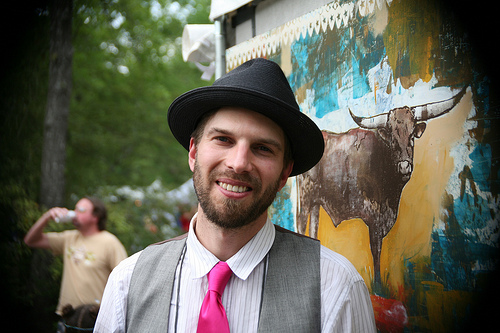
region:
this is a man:
[98, 74, 385, 331]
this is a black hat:
[131, 40, 331, 192]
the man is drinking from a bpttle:
[40, 201, 138, 328]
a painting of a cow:
[299, 96, 455, 257]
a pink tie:
[184, 264, 244, 329]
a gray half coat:
[134, 234, 333, 331]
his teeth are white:
[209, 169, 259, 209]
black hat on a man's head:
[161, 54, 329, 180]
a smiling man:
[93, 52, 383, 332]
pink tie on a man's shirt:
[189, 255, 232, 332]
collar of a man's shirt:
[178, 210, 283, 281]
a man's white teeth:
[216, 181, 248, 196]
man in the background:
[18, 191, 138, 331]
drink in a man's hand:
[53, 210, 75, 225]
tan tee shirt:
[52, 228, 131, 318]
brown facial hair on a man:
[188, 150, 286, 223]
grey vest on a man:
[124, 233, 317, 332]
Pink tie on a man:
[186, 255, 241, 330]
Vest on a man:
[119, 205, 322, 331]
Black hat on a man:
[146, 48, 327, 162]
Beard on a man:
[187, 133, 309, 244]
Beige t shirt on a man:
[53, 228, 128, 319]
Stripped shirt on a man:
[101, 209, 377, 330]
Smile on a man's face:
[206, 167, 259, 201]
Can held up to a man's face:
[48, 205, 90, 231]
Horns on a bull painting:
[338, 76, 478, 141]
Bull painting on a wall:
[288, 70, 475, 297]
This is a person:
[134, 55, 366, 332]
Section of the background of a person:
[18, 196, 102, 320]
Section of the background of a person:
[11, 69, 141, 193]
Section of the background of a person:
[337, 111, 454, 323]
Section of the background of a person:
[333, 6, 475, 163]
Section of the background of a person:
[27, 18, 168, 135]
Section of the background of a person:
[18, 130, 146, 255]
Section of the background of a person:
[182, 0, 364, 56]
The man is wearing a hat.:
[168, 54, 326, 224]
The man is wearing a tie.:
[196, 261, 234, 332]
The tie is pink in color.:
[196, 262, 236, 332]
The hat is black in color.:
[167, 57, 329, 231]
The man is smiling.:
[166, 59, 325, 229]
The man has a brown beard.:
[178, 123, 292, 233]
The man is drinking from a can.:
[36, 197, 110, 232]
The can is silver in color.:
[51, 206, 74, 225]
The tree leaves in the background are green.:
[81, 77, 166, 164]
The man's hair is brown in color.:
[73, 195, 113, 231]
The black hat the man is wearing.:
[173, 57, 322, 180]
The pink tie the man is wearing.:
[198, 264, 233, 331]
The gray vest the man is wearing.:
[120, 230, 319, 332]